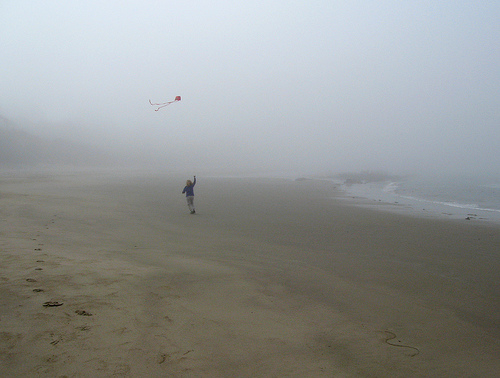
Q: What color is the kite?
A: Red.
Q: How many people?
A: One.